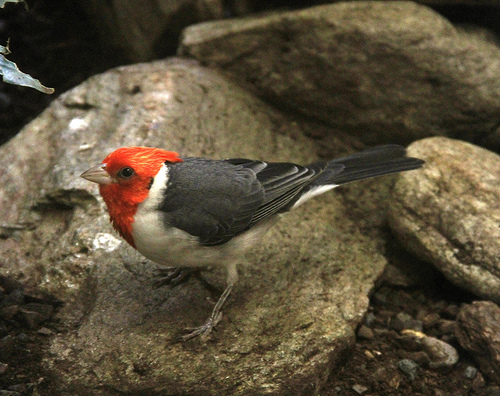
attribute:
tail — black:
[258, 129, 454, 223]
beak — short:
[79, 160, 116, 186]